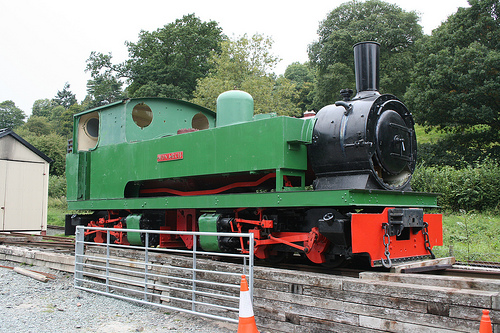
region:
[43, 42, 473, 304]
Green and orange steam engine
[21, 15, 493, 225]
A vintage train engine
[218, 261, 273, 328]
Orange and White Cone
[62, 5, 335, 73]
A Line of Trees In Background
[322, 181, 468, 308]
Orange Train Scoop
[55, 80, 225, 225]
The Conductor's Station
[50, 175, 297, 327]
A silver handrail in front of a train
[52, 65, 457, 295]
Historically Preserved Train Engine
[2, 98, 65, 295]
A small white shed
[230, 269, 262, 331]
an orange and white traffic cone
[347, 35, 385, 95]
the chimney of a train engine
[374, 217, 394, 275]
a chain on the train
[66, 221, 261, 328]
a gray railing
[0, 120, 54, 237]
a white and black shack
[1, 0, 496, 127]
a gray sky overhead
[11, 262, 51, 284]
a brown wooden plank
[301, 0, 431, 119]
a green tree behind the train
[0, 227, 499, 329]
a small brick wall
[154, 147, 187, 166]
a label on the train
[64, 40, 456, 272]
Older locomotive on the display.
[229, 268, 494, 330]
Warning cones in the area.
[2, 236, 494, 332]
Wooden railroad timbers by the train.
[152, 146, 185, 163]
Kind of locomotive on the train.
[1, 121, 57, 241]
Shed next to locomotive.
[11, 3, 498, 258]
Trees in the background.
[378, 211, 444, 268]
Chains on front of locomotive.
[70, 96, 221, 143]
Round windows in the locomotive.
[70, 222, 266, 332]
Metal fence in front of locomotive.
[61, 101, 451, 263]
Orange and green on the locomotive.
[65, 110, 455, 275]
Green train engine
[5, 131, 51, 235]
beige shed behind the train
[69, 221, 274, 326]
silver rail next tot the train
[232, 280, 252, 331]
Orange and white traffic cone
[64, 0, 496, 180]
trees on a hill behind the train engine.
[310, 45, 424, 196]
black steam engine at the front of the locomotive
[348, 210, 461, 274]
orange plate with giant hooks at the front of the train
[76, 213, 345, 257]
Red and black train wheels.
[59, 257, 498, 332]
stacked wood railroad ties next tot the train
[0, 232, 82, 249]
section of track right behind the train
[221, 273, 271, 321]
a white and orange cone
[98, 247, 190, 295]
a metal fence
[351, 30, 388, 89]
black top of a train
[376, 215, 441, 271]
chains on a train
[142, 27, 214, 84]
dark green tree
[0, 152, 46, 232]
a white building with a door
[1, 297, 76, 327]
grey gravel on the ground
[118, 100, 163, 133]
a circular hole in a train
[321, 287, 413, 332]
a small stack of wood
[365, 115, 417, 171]
the front of a train